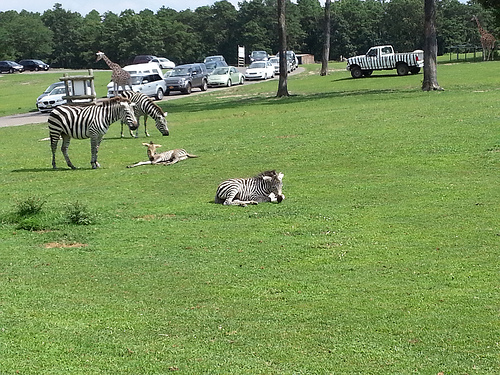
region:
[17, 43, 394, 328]
zebras in a field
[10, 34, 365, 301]
zebras on the grass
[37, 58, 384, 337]
adult zebras and young zebras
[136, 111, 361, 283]
zberas laying on the ground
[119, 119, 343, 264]
young zebras laying on the ground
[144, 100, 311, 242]
zebras laying on the ground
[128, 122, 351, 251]
young zebras laying in the grass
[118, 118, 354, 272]
zebras laying in the grass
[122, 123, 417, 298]
two zebras laying in the grass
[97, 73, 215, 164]
a zebra with its head down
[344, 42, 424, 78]
a truck painted like a zebra to blend in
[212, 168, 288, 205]
a zebra lounging on the grass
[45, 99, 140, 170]
a zebra standing on a grassy expanse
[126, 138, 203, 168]
this baby zebra looks pretty young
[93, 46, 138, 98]
a giraffe at a wild animal park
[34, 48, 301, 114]
a line of tourists in cars observes the wildlife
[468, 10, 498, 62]
a giraffe at a wild animal park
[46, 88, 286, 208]
several zebras at a wild animal park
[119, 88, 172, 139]
a zebra grazing at a wild animal park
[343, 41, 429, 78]
a staff truck keeps an eye on tourists and wild animals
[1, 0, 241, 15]
blue of daytime sky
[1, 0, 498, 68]
line of green trees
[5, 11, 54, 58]
green leaves on trees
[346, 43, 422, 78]
truck with painted stripes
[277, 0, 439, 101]
trunks of three trees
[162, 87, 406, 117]
tree shadows on grass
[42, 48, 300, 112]
line of cars on road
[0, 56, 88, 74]
two parked cars on lot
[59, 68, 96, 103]
back of sign on posts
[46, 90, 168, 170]
two zebra standing on grass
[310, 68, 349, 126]
part of a groind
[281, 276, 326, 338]
part of a fiedl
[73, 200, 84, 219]
;part of a plnat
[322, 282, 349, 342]
part of a ground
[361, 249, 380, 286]
part of a ground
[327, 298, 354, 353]
part of a ground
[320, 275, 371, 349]
part of a field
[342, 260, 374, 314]
part of a grass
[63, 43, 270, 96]
many cars running on the road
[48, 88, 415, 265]
zebras are standing and laying in the lawn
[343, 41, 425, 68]
truck parking in the lawn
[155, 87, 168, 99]
wheel on the car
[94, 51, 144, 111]
giraffe standing near the car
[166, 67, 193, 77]
front class with wiper in the car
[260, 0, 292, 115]
trees with branches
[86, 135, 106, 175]
legs of the zebra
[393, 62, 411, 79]
wheel of the truck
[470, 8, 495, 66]
trees with giraffe